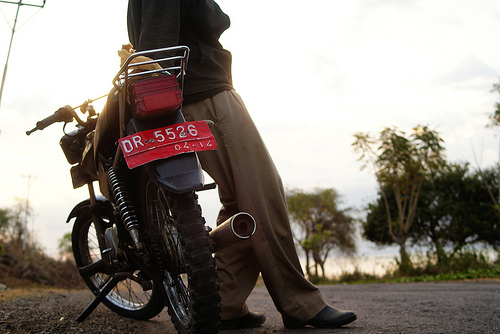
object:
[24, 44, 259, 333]
motorcycle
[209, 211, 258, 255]
exhast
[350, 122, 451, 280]
tree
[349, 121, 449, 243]
branches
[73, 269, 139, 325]
kickstand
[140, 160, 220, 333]
tire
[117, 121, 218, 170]
license plate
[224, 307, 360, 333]
shoes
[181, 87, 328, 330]
pants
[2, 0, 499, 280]
sky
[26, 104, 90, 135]
handle bar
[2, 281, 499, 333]
road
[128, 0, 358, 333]
person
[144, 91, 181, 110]
light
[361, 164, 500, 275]
trees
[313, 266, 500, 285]
grass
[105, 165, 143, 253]
shocks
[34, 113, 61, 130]
brake